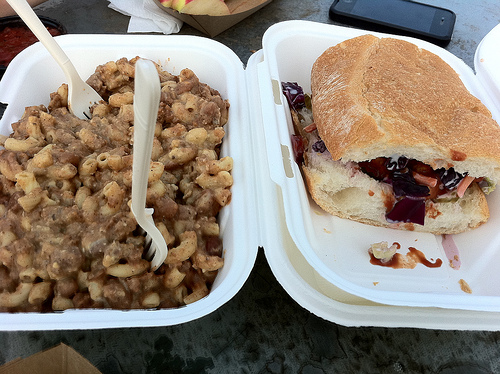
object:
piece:
[94, 150, 129, 170]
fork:
[128, 54, 172, 272]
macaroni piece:
[1, 272, 35, 309]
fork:
[4, 1, 108, 117]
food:
[0, 56, 238, 310]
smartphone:
[327, 0, 463, 47]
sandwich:
[282, 31, 496, 235]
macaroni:
[0, 59, 232, 315]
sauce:
[368, 240, 445, 275]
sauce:
[357, 155, 470, 225]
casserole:
[0, 57, 233, 292]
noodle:
[1, 121, 38, 151]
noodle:
[92, 151, 125, 167]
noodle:
[170, 139, 193, 160]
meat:
[31, 229, 74, 266]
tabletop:
[2, 0, 500, 374]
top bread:
[308, 30, 499, 189]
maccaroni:
[18, 186, 52, 212]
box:
[247, 20, 500, 331]